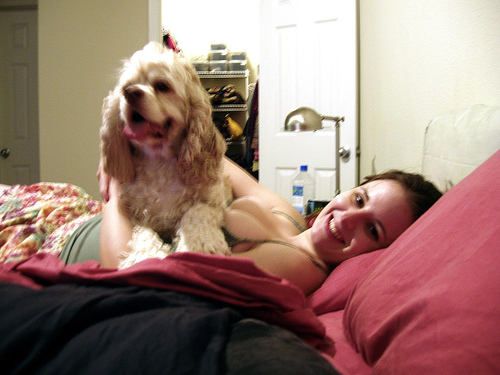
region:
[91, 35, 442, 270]
A woman lying in bed with a dog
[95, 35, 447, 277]
A woman lying in bed with a dog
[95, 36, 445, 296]
A woman lying in bed with a dog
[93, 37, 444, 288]
A woman lying in bed with a dog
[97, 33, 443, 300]
A woman lying in bed with a dog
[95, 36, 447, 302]
A woman lying in bed with a dog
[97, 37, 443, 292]
A woman lying in bed with a dog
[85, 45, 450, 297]
A woman lying in bed with a dog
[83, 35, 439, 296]
A woman lying in bed with a dog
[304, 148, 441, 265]
the head of a girl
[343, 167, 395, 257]
the eyes of a girl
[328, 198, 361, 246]
the nose of a girl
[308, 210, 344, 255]
the teeth of a girl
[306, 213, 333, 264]
the chin of a girl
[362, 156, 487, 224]
the hair of a girl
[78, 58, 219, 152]
the head of a dog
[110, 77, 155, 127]
the nose of a dog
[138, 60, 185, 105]
the eye of a dog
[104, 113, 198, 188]
the tongue of a dog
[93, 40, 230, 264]
Dog is sitting on the woman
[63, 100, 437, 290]
woman is laying on the bed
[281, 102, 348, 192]
silver lamp is next to bed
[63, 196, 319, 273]
woman is wearing gray tank top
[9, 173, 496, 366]
sheets on the bed are pink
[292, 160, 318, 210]
plastic bottle in front of white door.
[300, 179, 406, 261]
woman with smile on her face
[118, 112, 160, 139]
The dog's tongue is hanging out of his mouth.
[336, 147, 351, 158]
door knob is silver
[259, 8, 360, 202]
The closet door is white.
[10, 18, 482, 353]
A dog is sitting on his master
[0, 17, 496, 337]
A dog is enjoying some attention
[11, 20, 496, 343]
A dog is sticking his tongue out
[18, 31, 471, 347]
The person is enjoying their pet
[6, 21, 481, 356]
The person is laying on their bed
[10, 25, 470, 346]
The person's head is on a pillow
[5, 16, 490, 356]
The person is playing with the dog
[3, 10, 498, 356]
The person is inside a room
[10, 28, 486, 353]
The person is having a great time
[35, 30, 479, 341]
The person is enjoying their day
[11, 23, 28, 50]
square on wooden door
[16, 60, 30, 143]
square on wooden door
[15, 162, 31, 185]
square on wooden door